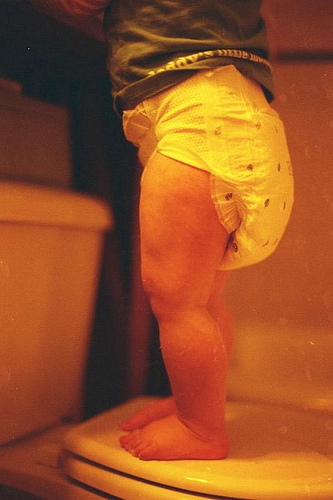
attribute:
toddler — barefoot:
[60, 3, 295, 460]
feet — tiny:
[118, 394, 228, 460]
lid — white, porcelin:
[61, 392, 332, 499]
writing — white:
[147, 49, 272, 78]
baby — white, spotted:
[119, 151, 293, 463]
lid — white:
[0, 178, 117, 277]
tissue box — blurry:
[2, 79, 75, 191]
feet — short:
[114, 399, 244, 461]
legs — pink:
[130, 204, 238, 429]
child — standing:
[88, 13, 253, 350]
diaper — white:
[110, 57, 298, 274]